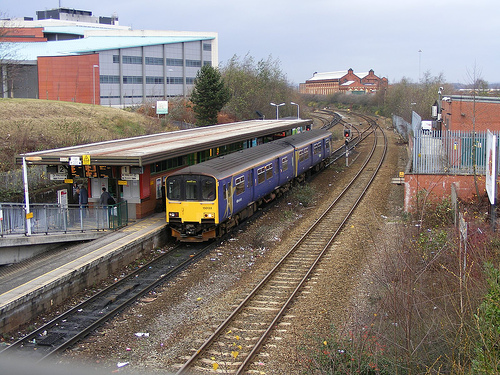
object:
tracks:
[0, 121, 381, 374]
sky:
[0, 0, 500, 87]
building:
[0, 12, 224, 110]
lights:
[343, 129, 352, 166]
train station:
[0, 108, 313, 305]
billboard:
[51, 158, 121, 184]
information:
[46, 159, 121, 181]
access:
[0, 203, 130, 250]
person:
[99, 187, 117, 222]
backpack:
[108, 197, 114, 205]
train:
[165, 130, 332, 248]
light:
[199, 210, 215, 220]